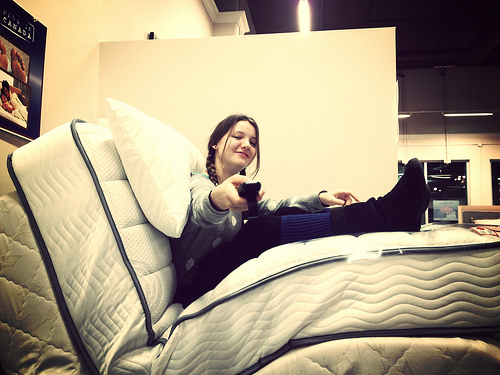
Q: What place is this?
A: Mattress store.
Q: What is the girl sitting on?
A: Bed.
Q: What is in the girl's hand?
A: Remote control.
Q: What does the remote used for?
A: Maneuver the bed.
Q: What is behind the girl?
A: Pillow.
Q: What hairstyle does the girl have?
A: Braids.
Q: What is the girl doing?
A: Smiling.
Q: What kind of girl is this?
A: Young.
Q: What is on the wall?
A: Poster.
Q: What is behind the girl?
A: White wall.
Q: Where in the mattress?
A: Inside the store.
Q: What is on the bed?
A: A pillow.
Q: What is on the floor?
A: A bed.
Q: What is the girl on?
A: A mattress.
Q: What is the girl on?
A: Mattress bed.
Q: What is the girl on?
A: A bed.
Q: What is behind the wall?
A: Wall divider.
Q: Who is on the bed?
A: A woman.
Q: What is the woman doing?
A: Holding a remote.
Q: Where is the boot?
A: On the girl.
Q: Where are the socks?
A: On the girl.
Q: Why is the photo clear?
A: The area is lit.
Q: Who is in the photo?
A: A lady.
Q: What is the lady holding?
A: A remote.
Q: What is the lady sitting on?
A: Bed.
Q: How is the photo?
A: Clear.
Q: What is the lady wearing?
A: Clothes.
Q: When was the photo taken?
A: Daytime.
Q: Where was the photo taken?
A: Mattress store.